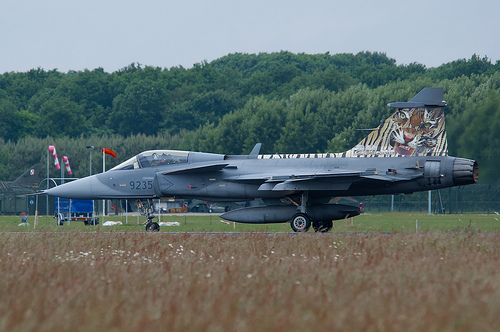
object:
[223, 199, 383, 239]
missles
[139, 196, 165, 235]
landing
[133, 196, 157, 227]
assembly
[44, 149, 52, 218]
pole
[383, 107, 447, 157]
tiger face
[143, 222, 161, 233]
wheel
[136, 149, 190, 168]
canopy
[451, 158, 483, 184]
nozzle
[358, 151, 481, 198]
jet engine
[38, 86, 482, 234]
jet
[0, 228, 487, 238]
runway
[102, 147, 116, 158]
windsock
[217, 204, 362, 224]
tank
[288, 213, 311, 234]
wheel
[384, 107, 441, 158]
tiger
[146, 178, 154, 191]
number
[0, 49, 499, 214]
tree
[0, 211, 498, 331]
field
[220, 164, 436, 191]
wing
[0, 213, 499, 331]
grass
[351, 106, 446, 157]
image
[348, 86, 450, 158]
tail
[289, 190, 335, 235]
landing gear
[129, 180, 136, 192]
numbers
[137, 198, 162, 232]
landing gear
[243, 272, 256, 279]
flowers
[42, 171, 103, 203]
nose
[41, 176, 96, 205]
nosecone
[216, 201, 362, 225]
bomb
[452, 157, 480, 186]
tail thruster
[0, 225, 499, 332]
bush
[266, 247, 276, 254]
flowers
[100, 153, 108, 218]
pole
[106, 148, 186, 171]
cockpit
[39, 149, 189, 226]
front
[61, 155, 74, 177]
banner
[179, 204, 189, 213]
barrel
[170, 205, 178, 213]
barrel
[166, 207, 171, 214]
barrel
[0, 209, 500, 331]
ground